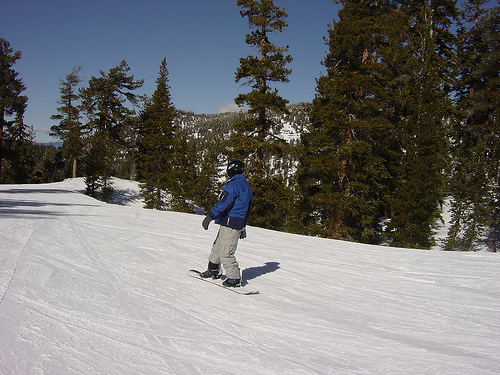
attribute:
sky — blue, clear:
[33, 8, 179, 50]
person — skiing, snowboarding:
[202, 152, 257, 300]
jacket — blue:
[208, 176, 252, 220]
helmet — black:
[225, 161, 247, 177]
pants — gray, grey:
[211, 220, 244, 281]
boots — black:
[204, 264, 246, 285]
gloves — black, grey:
[203, 211, 212, 230]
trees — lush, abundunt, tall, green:
[318, 20, 428, 241]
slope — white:
[47, 177, 170, 252]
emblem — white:
[228, 161, 238, 171]